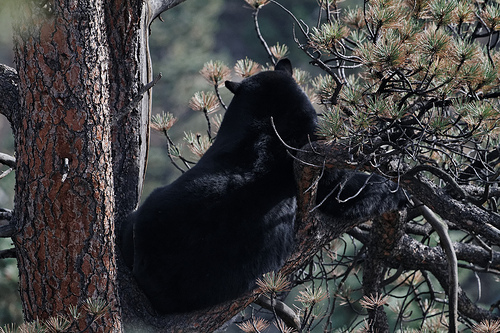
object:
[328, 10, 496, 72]
needles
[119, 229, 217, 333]
edge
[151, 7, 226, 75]
trees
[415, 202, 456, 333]
limb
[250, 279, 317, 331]
limb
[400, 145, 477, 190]
limb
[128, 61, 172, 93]
limb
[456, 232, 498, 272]
limb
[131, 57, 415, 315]
bear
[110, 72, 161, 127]
limb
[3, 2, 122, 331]
tree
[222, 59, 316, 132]
head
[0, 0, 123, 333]
tree trunks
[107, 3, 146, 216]
tree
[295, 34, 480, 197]
limbs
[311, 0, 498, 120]
green/brown leaves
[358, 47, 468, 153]
needles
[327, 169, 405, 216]
arm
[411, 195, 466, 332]
limb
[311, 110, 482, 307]
tree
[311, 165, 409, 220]
leg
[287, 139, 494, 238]
limb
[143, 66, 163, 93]
limb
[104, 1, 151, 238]
trunk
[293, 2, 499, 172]
leaves